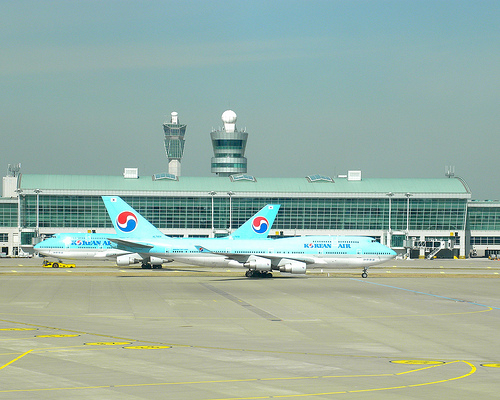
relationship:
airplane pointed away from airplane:
[101, 195, 398, 277] [34, 204, 282, 268]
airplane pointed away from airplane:
[34, 204, 282, 268] [101, 195, 398, 277]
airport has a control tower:
[1, 109, 499, 399] [210, 109, 248, 176]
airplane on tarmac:
[101, 195, 398, 277] [1, 258, 499, 399]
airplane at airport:
[101, 195, 398, 277] [1, 109, 499, 399]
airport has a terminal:
[1, 109, 499, 399] [1, 162, 499, 259]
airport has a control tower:
[1, 109, 499, 399] [162, 111, 187, 177]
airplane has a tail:
[101, 195, 398, 277] [102, 196, 174, 262]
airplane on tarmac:
[34, 204, 282, 268] [1, 258, 499, 399]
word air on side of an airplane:
[338, 244, 351, 249] [101, 195, 398, 277]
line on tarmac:
[0, 305, 492, 319] [1, 258, 499, 399]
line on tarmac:
[0, 360, 460, 392] [1, 258, 499, 399]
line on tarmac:
[0, 360, 477, 400] [1, 258, 499, 399]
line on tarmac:
[0, 345, 89, 371] [1, 258, 499, 399]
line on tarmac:
[0, 346, 122, 356] [1, 258, 499, 399]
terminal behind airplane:
[1, 162, 499, 259] [101, 195, 398, 277]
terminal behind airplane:
[1, 162, 499, 259] [34, 204, 282, 268]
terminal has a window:
[1, 162, 499, 259] [469, 236, 475, 245]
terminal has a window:
[1, 162, 499, 259] [474, 236, 481, 245]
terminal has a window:
[1, 162, 499, 259] [480, 236, 488, 246]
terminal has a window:
[1, 162, 499, 259] [487, 236, 494, 245]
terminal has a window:
[1, 162, 499, 259] [493, 236, 500, 245]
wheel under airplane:
[158, 265, 162, 269] [34, 204, 282, 268]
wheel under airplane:
[152, 264, 157, 268] [34, 204, 282, 268]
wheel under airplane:
[147, 264, 152, 268] [34, 204, 282, 268]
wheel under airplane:
[141, 264, 146, 268] [34, 204, 282, 268]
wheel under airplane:
[267, 273, 271, 278] [101, 195, 398, 277]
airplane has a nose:
[101, 195, 398, 277] [378, 242, 398, 266]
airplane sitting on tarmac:
[101, 195, 398, 277] [1, 258, 499, 399]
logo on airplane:
[116, 211, 139, 233] [101, 195, 398, 277]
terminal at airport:
[1, 162, 499, 259] [1, 109, 499, 399]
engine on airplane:
[243, 259, 271, 271] [101, 195, 398, 277]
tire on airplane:
[361, 273, 368, 279] [101, 195, 398, 277]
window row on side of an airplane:
[173, 250, 391, 254] [101, 195, 398, 277]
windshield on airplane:
[371, 239, 377, 243] [101, 195, 398, 277]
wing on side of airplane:
[195, 245, 327, 266] [101, 195, 398, 277]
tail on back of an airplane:
[102, 196, 174, 262] [101, 195, 398, 277]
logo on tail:
[116, 211, 139, 233] [102, 196, 174, 262]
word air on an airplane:
[338, 244, 351, 249] [101, 195, 398, 277]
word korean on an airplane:
[303, 243, 331, 248] [101, 195, 398, 277]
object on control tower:
[221, 110, 237, 132] [210, 109, 248, 176]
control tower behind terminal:
[210, 109, 248, 176] [1, 162, 499, 259]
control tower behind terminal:
[162, 111, 187, 177] [1, 162, 499, 259]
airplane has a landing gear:
[101, 195, 398, 277] [361, 267, 367, 278]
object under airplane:
[44, 262, 76, 269] [34, 204, 282, 268]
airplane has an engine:
[101, 195, 398, 277] [243, 259, 271, 271]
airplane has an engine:
[101, 195, 398, 277] [279, 262, 306, 273]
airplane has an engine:
[34, 204, 282, 268] [116, 256, 138, 266]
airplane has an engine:
[34, 204, 282, 268] [150, 256, 171, 265]